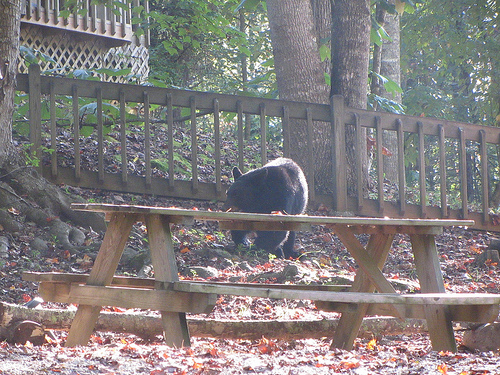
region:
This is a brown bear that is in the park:
[242, 149, 327, 299]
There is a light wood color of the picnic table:
[228, 284, 233, 299]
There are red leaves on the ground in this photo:
[311, 353, 319, 370]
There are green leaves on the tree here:
[430, 30, 469, 105]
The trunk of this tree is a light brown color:
[3, 85, 23, 139]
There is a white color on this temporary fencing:
[135, 62, 145, 78]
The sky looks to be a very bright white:
[256, 55, 261, 65]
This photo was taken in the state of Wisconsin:
[105, 31, 365, 370]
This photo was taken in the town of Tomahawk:
[99, 17, 369, 348]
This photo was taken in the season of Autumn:
[89, 39, 348, 340]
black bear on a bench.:
[208, 150, 318, 252]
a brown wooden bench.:
[20, 200, 498, 353]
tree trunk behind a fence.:
[263, 0, 371, 202]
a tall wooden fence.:
[19, 0, 150, 86]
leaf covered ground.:
[0, 191, 498, 373]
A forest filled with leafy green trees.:
[147, 0, 498, 208]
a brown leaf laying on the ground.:
[360, 336, 380, 353]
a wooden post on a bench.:
[159, 308, 191, 353]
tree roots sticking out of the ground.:
[0, 186, 192, 255]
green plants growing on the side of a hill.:
[12, 39, 207, 174]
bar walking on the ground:
[213, 146, 322, 255]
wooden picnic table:
[29, 173, 496, 358]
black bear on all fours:
[216, 148, 313, 264]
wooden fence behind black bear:
[21, 58, 490, 264]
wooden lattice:
[20, 41, 156, 83]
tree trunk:
[263, 21, 353, 193]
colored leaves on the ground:
[201, 335, 353, 374]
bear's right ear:
[230, 162, 246, 182]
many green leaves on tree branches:
[141, 8, 236, 60]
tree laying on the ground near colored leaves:
[15, 299, 431, 352]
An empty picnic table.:
[143, 170, 392, 352]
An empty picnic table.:
[101, 223, 319, 348]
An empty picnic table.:
[308, 181, 439, 332]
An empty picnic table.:
[133, 181, 288, 308]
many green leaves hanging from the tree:
[405, 3, 498, 116]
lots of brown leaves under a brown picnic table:
[23, 202, 499, 374]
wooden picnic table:
[21, 199, 498, 359]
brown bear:
[216, 156, 308, 258]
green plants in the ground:
[228, 240, 272, 267]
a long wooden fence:
[1, 65, 499, 230]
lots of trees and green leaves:
[151, 1, 497, 88]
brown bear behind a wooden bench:
[21, 156, 498, 368]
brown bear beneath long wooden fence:
[3, 63, 498, 258]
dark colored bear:
[219, 154, 309, 259]